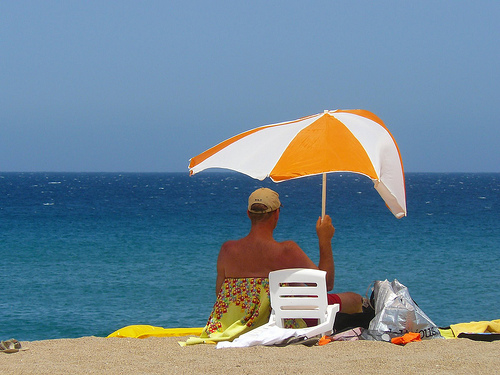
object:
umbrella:
[187, 108, 408, 220]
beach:
[0, 318, 500, 375]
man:
[216, 188, 364, 313]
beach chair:
[239, 268, 339, 347]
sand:
[0, 336, 499, 374]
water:
[0, 173, 499, 341]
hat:
[248, 187, 284, 213]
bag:
[356, 278, 445, 340]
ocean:
[1, 172, 499, 342]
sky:
[0, 2, 497, 175]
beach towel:
[178, 278, 308, 348]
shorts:
[304, 292, 342, 326]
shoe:
[0, 338, 22, 354]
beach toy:
[107, 324, 206, 339]